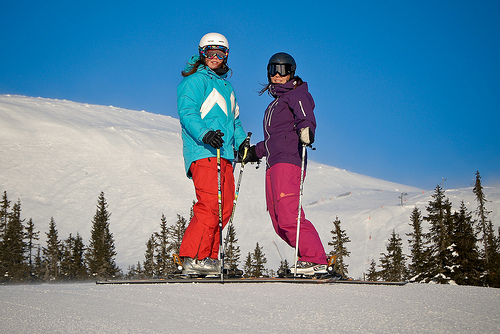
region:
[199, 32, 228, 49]
the woman is wearing a helmet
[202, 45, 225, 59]
the woman is wearing goggles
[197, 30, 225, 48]
the helmet is white in color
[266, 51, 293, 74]
the woman is wearing a helmet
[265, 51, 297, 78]
the helmet is black in color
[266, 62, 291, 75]
the woman is wearing goggles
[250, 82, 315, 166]
the woman is wearing a jacket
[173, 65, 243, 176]
the jacket is green in color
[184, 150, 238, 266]
the woman is wearing ski pants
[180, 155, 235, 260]
the pants are red in color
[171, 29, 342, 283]
TWO WOMEN ON SKIS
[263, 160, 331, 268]
A PAIR OF PINK SKI PANTS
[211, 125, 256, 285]
A PAIR OF SKI POLES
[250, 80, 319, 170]
A PURPLE SKI JACKET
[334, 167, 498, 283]
TREES IN THE DISTANCE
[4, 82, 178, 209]
A SNOW COVERED MOUNTAIN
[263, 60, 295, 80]
A PAIR OF SKI GOGGLES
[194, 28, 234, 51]
A WHITE SKI HELMET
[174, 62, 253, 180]
AN AQUA SKI JACKET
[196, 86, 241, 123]
A WHITE DESIGN ON A SKI JACKET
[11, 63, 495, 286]
Snow covered mountain behind skiers.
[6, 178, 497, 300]
Green trees in background.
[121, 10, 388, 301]
Two women skiers posing for picture.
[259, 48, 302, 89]
A pair of black ski goggles.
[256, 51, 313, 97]
A black safety helmet.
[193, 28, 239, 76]
A white safety helmet.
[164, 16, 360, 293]
Two women on skis.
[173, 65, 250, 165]
A light blue coat with white design.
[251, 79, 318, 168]
A purple coat.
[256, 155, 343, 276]
A pair of pink pants.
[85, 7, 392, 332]
two woman on skies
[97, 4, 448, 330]
two woman that are skiing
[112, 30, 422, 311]
two woman on the snow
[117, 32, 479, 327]
two woman skiing on snow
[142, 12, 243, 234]
a woman wearing a helmet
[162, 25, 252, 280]
a woman wearing a white helmet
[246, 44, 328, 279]
a woman wearing a purple jacket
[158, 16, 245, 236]
a woman wearing a blue jacket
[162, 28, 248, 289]
a woman wearing red pants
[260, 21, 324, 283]
a woman wearing pink pants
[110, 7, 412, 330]
Two girls skiing on the mountain.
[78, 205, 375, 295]
Skis under the women.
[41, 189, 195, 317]
Trees on the hill.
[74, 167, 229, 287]
Pine trees on the snow.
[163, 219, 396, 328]
Snow boots on the skis.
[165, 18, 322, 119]
Girls wearing helmets.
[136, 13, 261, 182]
Girl with a blue and white coat.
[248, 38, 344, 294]
Girl wearing pink and purple.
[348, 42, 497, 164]
Blue sky over the mountain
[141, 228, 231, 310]
Silver ski boots on the woman.